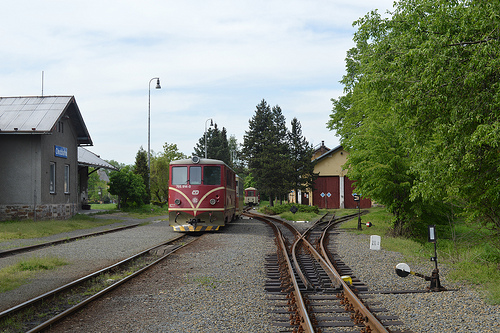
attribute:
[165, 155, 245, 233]
train — red, tan, yellow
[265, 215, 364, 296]
train track — gray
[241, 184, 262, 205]
train — black, white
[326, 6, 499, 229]
trees — green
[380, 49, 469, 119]
leaves — green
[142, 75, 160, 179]
street light — hook shaped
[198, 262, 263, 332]
gravel — gray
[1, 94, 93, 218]
building — grey, gray, tan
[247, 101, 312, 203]
pine trees — green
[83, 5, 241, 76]
clouds — white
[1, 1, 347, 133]
sky — blue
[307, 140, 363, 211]
building — tan, red, yellow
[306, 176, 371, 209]
doors — burgandy, red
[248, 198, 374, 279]
tracks — three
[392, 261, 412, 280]
signal — black, white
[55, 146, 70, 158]
sign — blue, white